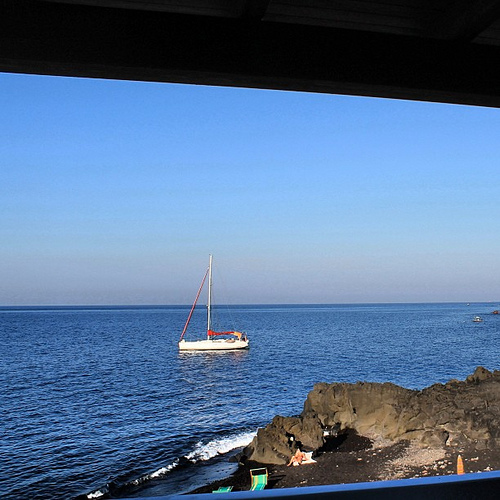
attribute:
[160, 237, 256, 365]
white sailboat — white 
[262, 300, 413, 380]
water — blue 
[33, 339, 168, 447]
water — calm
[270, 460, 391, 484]
soil — black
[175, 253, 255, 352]
white boat — white 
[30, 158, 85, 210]
white clouds — white 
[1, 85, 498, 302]
blue sky — blue 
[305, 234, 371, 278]
white clouds — white 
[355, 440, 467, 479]
rocks — brown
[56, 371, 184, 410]
waves — crashing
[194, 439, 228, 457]
waves — white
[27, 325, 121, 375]
water — blue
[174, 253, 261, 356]
boat — white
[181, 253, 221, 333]
mast — tall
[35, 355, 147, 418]
water — large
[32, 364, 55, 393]
water — large, blue 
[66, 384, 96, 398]
water — large